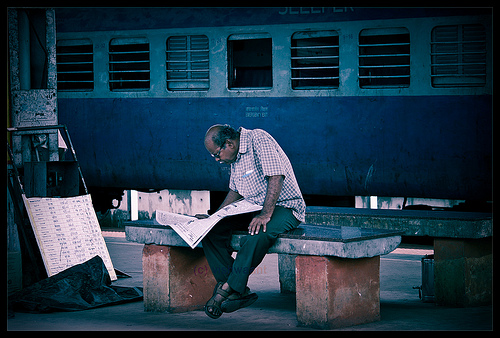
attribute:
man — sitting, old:
[203, 124, 307, 320]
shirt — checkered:
[229, 127, 307, 224]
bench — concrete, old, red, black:
[125, 224, 404, 328]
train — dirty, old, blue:
[56, 8, 497, 127]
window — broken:
[227, 33, 274, 92]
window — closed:
[431, 24, 486, 89]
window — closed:
[166, 35, 209, 92]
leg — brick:
[294, 256, 380, 327]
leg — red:
[143, 244, 204, 313]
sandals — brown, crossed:
[204, 281, 258, 319]